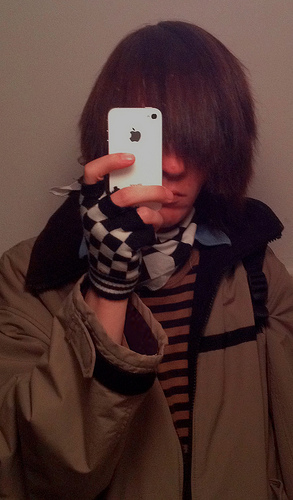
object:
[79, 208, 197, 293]
bandanna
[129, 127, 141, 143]
apple logo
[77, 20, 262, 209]
hair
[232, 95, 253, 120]
ground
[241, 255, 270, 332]
strap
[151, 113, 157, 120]
camera lens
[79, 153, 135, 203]
finger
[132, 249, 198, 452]
shirt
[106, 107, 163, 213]
apple phone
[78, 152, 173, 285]
hand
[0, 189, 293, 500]
jacket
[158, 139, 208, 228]
face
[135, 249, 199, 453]
stripe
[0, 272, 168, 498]
jacket sleeve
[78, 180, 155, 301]
glove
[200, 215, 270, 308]
shoulder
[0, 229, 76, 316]
shoulder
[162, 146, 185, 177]
nose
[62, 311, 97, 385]
velco strap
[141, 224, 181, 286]
neck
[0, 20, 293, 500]
man